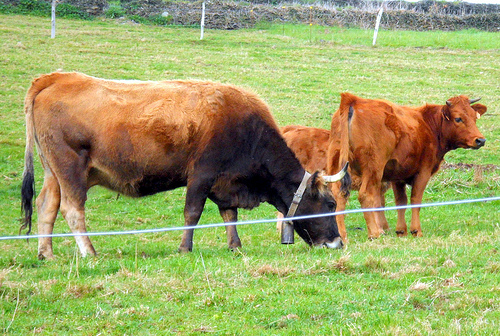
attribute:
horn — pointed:
[320, 160, 351, 187]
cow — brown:
[19, 69, 351, 259]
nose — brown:
[469, 135, 490, 154]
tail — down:
[13, 75, 50, 242]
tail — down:
[335, 93, 354, 193]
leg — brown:
[177, 156, 211, 252]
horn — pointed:
[465, 94, 487, 108]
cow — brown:
[326, 86, 486, 242]